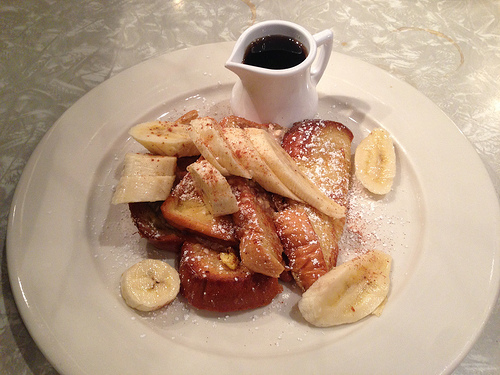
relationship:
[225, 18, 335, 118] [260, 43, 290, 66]
pitcher of syrup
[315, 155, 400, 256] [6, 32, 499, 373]
sugar on plate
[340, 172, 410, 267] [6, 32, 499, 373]
cinnamon on plate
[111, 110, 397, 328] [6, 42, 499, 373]
bananas on plate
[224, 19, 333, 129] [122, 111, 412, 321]
cup for food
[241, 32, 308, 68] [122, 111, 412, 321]
syrup for food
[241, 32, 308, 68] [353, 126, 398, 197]
syrup for banana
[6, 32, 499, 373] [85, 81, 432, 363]
plate has round indention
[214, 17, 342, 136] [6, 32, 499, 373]
syrup on plate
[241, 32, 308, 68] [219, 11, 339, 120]
syrup in cup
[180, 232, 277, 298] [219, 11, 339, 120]
brown syrup in cup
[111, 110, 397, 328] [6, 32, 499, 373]
bananas in plate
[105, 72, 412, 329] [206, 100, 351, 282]
bananas on toast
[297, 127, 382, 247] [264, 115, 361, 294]
sugar on toast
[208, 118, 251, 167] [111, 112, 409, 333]
cinnamon on bananas